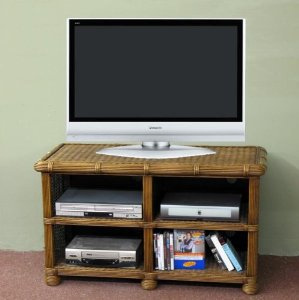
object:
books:
[153, 229, 244, 273]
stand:
[45, 275, 61, 288]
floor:
[0, 252, 299, 300]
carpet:
[0, 250, 299, 300]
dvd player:
[160, 193, 242, 223]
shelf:
[44, 213, 259, 231]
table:
[33, 137, 270, 297]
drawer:
[53, 225, 144, 268]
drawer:
[152, 177, 249, 223]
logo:
[149, 126, 163, 129]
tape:
[205, 232, 243, 272]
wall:
[0, 6, 34, 206]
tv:
[66, 16, 246, 160]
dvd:
[153, 231, 174, 271]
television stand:
[33, 144, 269, 295]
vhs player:
[64, 234, 143, 268]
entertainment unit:
[33, 141, 268, 295]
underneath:
[46, 276, 259, 296]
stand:
[95, 141, 216, 160]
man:
[180, 232, 193, 253]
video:
[205, 230, 243, 272]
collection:
[153, 229, 243, 271]